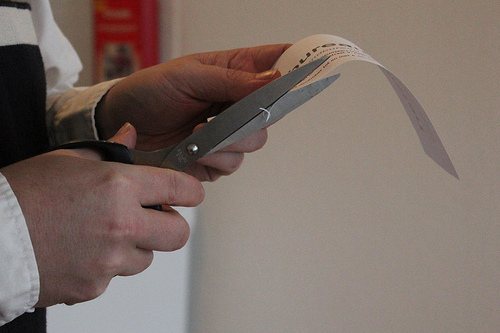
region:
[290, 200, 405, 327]
the walls behind the man are void of color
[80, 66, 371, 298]
a man holding scissors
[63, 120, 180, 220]
the scissors handle is black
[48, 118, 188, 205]
his thumb is through the hole handle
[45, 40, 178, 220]
the man is wearing a long sleeved shirt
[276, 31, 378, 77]
the paper is white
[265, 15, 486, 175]
the paper has black writing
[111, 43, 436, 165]
the man is holding the paper in left hand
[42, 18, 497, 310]
picture taken indoors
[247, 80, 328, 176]
a sliver a paper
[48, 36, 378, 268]
A person is holding sissoers.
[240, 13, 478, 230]
The person is holding the paper in one hand.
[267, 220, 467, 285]
The wall is white.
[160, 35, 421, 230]
The scissors are cutting the paper.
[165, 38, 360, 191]
Two blades on the pair of scissors.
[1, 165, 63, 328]
The cuff on the shirt is white.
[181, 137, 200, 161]
A screw holds the blades of the scissors together.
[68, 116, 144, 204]
A thumb is placed through the handle on the scissors.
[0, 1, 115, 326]
The shirt is black and white.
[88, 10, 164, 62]
A blury red object in the background.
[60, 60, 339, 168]
pair of scissors used for cutting paper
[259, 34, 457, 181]
piece of paper that is being cut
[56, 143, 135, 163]
black handle on the scissors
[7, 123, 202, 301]
a person's right hand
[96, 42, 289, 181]
a person's left hand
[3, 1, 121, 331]
black and white shirt on the person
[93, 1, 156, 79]
blurry red object in the background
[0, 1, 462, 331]
person cutting a piece of paper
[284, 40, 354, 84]
black text on the paper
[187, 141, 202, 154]
silver screw on the side of the scissors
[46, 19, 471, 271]
Hands holding scissors cutting paper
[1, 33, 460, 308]
Caucasian hands cutting paper with scissors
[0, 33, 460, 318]
Hands cutting a slip of paper with scissors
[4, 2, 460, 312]
Cutting paper with black scissors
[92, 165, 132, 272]
Knuckles on a hand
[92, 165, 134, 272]
Caucasian hand's knuckles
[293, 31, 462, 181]
Tip of scissors cutting paper slip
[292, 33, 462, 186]
Scissors cutting in to paper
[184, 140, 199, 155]
Screw that holds scissor blades together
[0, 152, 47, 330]
White fabric wrist cuff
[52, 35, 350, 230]
A person is holding scissors.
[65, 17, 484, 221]
The scissors cuts a piece of paper.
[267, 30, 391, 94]
The paper has lettering on it.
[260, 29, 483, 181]
The paper is white.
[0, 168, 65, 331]
The person wears a white shirt.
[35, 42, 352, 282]
The scissors are on the right hand.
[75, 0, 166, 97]
A red object is on the wall.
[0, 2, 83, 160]
The person's shirt is black and white.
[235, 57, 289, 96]
The person's fingernails are short.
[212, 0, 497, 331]
A beige wall is in the background.